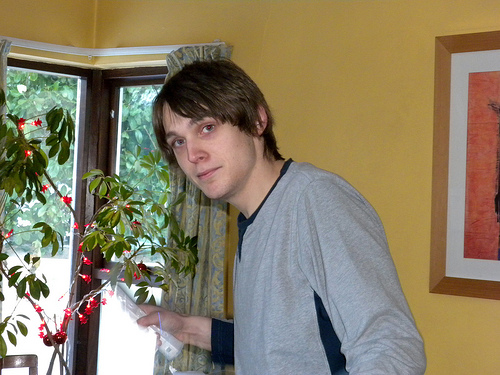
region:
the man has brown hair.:
[149, 59, 282, 167]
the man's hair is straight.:
[151, 59, 281, 164]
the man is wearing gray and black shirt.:
[228, 162, 425, 373]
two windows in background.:
[1, 51, 223, 373]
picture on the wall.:
[429, 27, 499, 299]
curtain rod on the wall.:
[1, 30, 230, 60]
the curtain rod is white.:
[3, 34, 228, 56]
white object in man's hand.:
[107, 278, 182, 361]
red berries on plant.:
[61, 300, 106, 322]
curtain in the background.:
[154, 42, 230, 374]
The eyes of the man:
[175, 122, 211, 148]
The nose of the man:
[186, 137, 207, 162]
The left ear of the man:
[255, 101, 266, 136]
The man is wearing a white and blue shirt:
[211, 157, 425, 373]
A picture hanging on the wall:
[428, 30, 499, 299]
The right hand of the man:
[134, 305, 197, 342]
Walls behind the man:
[1, 2, 498, 374]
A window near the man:
[1, 65, 166, 374]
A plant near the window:
[0, 88, 197, 373]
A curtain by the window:
[150, 47, 227, 374]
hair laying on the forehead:
[159, 91, 214, 121]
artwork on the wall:
[425, 30, 499, 305]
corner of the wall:
[88, 0, 102, 68]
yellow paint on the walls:
[0, 0, 498, 373]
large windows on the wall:
[0, 50, 224, 373]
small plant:
[0, 85, 205, 373]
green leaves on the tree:
[64, 140, 214, 319]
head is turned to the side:
[140, 58, 306, 228]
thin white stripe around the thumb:
[156, 308, 165, 331]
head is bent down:
[140, 63, 311, 238]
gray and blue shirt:
[184, 155, 432, 374]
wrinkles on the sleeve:
[344, 317, 438, 373]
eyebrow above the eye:
[158, 128, 188, 150]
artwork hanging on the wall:
[416, 27, 498, 303]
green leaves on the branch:
[39, 104, 83, 164]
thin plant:
[0, 80, 205, 372]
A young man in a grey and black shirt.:
[132, 55, 425, 373]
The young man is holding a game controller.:
[108, 58, 427, 373]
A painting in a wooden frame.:
[425, 21, 497, 306]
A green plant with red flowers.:
[5, 96, 206, 373]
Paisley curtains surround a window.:
[2, 40, 232, 373]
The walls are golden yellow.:
[0, 3, 494, 370]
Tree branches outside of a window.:
[2, 82, 170, 256]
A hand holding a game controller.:
[104, 280, 234, 369]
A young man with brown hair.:
[147, 58, 277, 205]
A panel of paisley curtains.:
[162, 34, 234, 371]